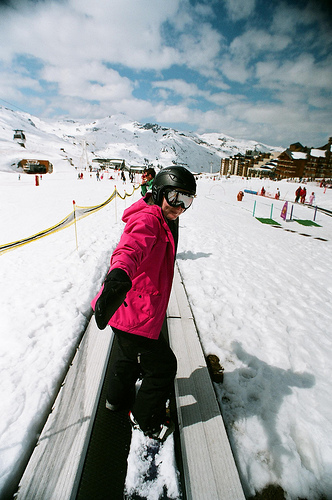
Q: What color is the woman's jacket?
A: Pink.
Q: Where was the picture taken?
A: At ski slopes.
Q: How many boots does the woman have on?
A: Two.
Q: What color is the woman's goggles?
A: Black.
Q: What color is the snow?
A: White.